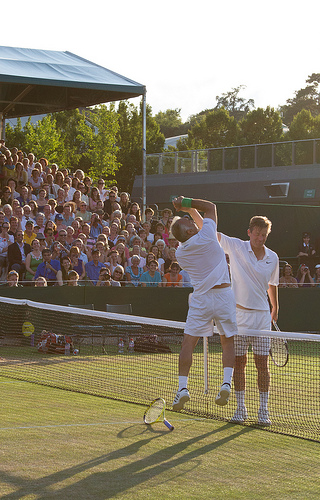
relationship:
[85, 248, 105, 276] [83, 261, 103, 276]
man wearing shirt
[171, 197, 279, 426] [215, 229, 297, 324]
man wearing shirt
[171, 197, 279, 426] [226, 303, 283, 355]
man wearing shorts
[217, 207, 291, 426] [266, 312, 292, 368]
man holding racket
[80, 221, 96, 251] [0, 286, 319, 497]
person looking at court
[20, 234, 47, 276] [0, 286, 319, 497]
person looking at court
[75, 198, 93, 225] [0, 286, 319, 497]
person looking at court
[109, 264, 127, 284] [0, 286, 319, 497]
person looking at court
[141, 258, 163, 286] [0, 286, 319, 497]
person looking at court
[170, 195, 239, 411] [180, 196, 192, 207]
man wearing wristband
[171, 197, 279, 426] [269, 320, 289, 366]
man holding racket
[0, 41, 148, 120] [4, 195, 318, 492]
canopy at tennis match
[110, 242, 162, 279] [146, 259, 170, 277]
member wearing shirt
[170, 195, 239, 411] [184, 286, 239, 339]
man wearing short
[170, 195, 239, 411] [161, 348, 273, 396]
man wearing socks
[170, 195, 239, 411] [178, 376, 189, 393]
man wearing sock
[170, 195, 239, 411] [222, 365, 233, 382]
man wearing sock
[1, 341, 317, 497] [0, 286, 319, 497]
grass in court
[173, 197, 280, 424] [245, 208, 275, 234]
man has hair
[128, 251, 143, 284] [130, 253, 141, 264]
woman has hair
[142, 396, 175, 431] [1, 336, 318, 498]
racket on ground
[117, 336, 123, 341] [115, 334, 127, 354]
cap on bottle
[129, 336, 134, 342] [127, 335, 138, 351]
cap on bottle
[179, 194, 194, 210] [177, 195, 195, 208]
sweatband on wrist